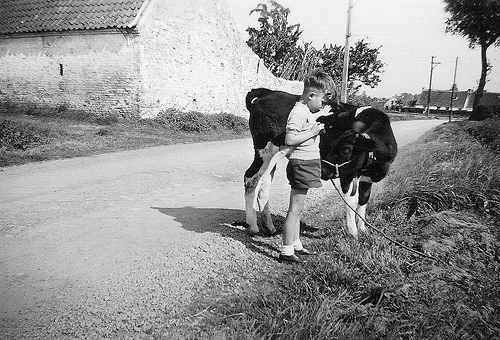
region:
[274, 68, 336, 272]
young boy standing with cow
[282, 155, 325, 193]
boy's casual cotton shorts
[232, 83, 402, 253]
black and white cow near boy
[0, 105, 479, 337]
country dirt road near boy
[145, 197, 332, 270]
shadow of boy and cow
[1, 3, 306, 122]
white stone building in background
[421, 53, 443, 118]
tall wooden pole in background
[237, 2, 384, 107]
row of trees in background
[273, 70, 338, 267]
boy petting nearby cow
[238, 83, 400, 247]
cow putting it's face near boy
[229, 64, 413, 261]
little boy petting a calf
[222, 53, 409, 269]
little boy standing by a calf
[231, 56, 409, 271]
calf sniffing a little boy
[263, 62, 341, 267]
little boy with short hair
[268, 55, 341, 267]
little boy wearing dark colored shorts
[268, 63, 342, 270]
little boy wearing light colored shirt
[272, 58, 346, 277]
little boy wearing collared shirt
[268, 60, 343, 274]
little boy wearing socks and shoes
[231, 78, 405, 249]
black and white calf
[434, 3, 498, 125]
tall shady tree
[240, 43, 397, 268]
child standing next to cow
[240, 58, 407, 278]
cow standing on road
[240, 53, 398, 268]
child and cow on road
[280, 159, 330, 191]
small child wearing shorts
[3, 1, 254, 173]
house near the road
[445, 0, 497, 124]
tall leafy tree in back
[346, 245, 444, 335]
grassy vegetation near road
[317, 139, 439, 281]
rope around cow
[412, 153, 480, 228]
grassy vegetation near road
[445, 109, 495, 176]
grassy vegetation near road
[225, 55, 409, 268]
boy and cow standing in road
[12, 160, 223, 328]
an empty gravel covered road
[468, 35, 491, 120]
crooked branch of a tall tree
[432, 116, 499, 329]
grassy area on the side of the road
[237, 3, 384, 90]
group of tall trees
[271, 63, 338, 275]
a young adolescent boy petting a cow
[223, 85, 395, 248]
a black and white cow on a rope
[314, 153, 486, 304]
a rope harness on the black and white cow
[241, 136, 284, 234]
black and white rear legs of calf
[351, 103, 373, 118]
white patch on cows back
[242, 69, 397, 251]
boy with a calf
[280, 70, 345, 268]
boy standing next to calf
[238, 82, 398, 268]
black and white calf next to boy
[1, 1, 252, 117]
old building in background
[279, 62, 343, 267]
boy in shorts and shirt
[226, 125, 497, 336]
grass on ground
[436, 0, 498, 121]
large tree in distance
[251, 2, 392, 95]
trees in front of house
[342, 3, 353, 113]
pole in ground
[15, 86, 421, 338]
boy and calf standing on side of road